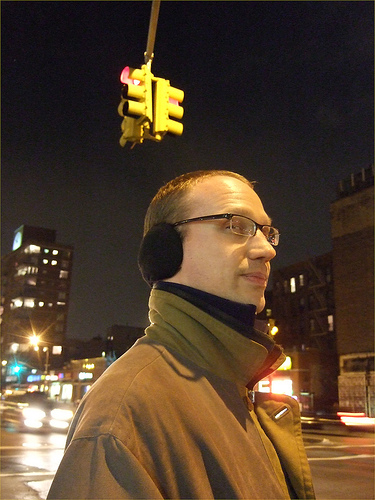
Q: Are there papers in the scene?
A: No, there are no papers.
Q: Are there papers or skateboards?
A: No, there are no papers or skateboards.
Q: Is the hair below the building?
A: Yes, the hair is below the building.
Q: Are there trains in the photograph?
A: No, there are no trains.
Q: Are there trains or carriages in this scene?
A: No, there are no trains or carriages.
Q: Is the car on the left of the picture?
A: Yes, the car is on the left of the image.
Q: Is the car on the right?
A: No, the car is on the left of the image.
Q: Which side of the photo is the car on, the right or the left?
A: The car is on the left of the image.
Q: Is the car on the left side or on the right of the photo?
A: The car is on the left of the image.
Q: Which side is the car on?
A: The car is on the left of the image.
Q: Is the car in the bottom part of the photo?
A: Yes, the car is in the bottom of the image.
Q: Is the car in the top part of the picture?
A: No, the car is in the bottom of the image.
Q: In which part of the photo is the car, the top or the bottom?
A: The car is in the bottom of the image.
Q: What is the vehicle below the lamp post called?
A: The vehicle is a car.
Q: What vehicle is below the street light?
A: The vehicle is a car.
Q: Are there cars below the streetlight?
A: Yes, there is a car below the streetlight.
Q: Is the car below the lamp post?
A: Yes, the car is below the lamp post.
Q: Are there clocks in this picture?
A: No, there are no clocks.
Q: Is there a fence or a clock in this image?
A: No, there are no clocks or fences.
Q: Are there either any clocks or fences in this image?
A: No, there are no clocks or fences.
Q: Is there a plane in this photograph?
A: No, there are no airplanes.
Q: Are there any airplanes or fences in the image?
A: No, there are no airplanes or fences.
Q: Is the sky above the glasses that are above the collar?
A: Yes, the sky is above the glasses.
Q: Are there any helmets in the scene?
A: No, there are no helmets.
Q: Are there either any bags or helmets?
A: No, there are no helmets or bags.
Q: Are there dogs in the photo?
A: No, there are no dogs.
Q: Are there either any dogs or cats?
A: No, there are no dogs or cats.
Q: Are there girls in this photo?
A: No, there are no girls.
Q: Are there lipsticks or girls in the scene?
A: No, there are no girls or lipsticks.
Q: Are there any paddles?
A: No, there are no paddles.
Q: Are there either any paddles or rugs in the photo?
A: No, there are no paddles or rugs.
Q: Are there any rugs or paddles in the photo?
A: No, there are no paddles or rugs.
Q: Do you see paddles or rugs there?
A: No, there are no paddles or rugs.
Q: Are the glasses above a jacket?
A: Yes, the glasses are above a jacket.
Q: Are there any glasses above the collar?
A: Yes, there are glasses above the collar.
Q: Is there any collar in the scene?
A: Yes, there is a collar.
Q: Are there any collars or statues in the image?
A: Yes, there is a collar.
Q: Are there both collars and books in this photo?
A: No, there is a collar but no books.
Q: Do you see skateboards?
A: No, there are no skateboards.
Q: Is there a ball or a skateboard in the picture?
A: No, there are no skateboards or balls.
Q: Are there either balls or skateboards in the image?
A: No, there are no skateboards or balls.